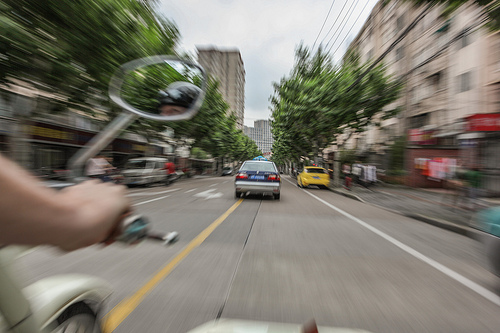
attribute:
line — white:
[281, 171, 485, 301]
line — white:
[280, 170, 485, 319]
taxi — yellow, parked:
[293, 161, 334, 193]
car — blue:
[229, 156, 287, 203]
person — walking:
[156, 150, 178, 187]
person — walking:
[81, 146, 124, 184]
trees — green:
[291, 68, 366, 170]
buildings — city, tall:
[186, 33, 288, 161]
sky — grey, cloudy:
[214, 14, 294, 44]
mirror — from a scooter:
[76, 24, 239, 128]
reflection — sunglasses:
[142, 77, 201, 121]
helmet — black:
[133, 75, 215, 123]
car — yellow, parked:
[286, 153, 337, 192]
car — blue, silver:
[219, 149, 284, 200]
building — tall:
[199, 52, 307, 159]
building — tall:
[229, 102, 294, 152]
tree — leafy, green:
[287, 51, 375, 157]